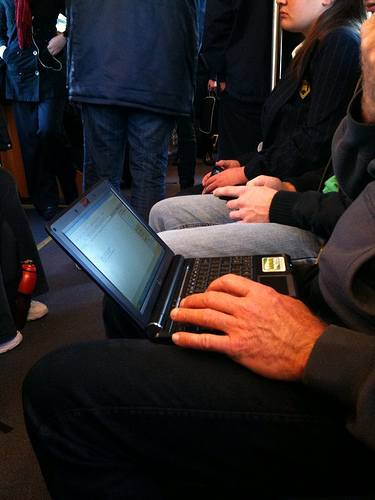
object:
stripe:
[120, 406, 153, 416]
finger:
[169, 306, 233, 330]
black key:
[188, 253, 257, 273]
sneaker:
[26, 300, 49, 319]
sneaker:
[0, 329, 23, 354]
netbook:
[44, 181, 307, 344]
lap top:
[42, 176, 299, 343]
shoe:
[25, 299, 52, 322]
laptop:
[42, 157, 299, 345]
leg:
[20, 339, 342, 500]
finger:
[204, 272, 252, 294]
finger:
[171, 330, 230, 353]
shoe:
[39, 199, 54, 221]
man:
[17, 10, 375, 500]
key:
[189, 257, 210, 286]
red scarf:
[13, 1, 29, 50]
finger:
[175, 291, 239, 316]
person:
[0, 3, 69, 232]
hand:
[169, 265, 327, 386]